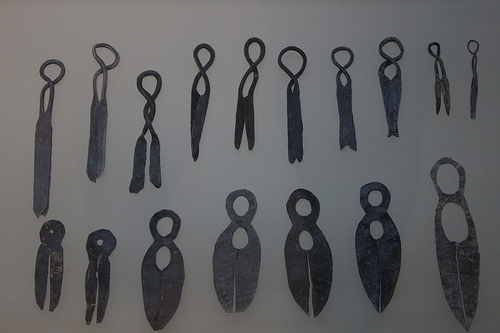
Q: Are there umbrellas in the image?
A: No, there are no umbrellas.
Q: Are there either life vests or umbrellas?
A: No, there are no umbrellas or life vests.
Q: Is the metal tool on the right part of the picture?
A: Yes, the tool is on the right of the image.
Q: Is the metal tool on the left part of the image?
A: No, the tool is on the right of the image.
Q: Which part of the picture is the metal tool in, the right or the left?
A: The tool is on the right of the image.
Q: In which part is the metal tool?
A: The tool is on the right of the image.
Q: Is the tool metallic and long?
A: Yes, the tool is metallic and long.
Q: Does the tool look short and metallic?
A: No, the tool is metallic but long.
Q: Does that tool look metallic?
A: Yes, the tool is metallic.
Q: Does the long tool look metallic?
A: Yes, the tool is metallic.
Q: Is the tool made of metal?
A: Yes, the tool is made of metal.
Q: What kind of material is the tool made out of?
A: The tool is made of metal.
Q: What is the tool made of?
A: The tool is made of metal.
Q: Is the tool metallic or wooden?
A: The tool is metallic.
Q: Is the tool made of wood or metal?
A: The tool is made of metal.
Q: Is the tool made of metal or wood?
A: The tool is made of metal.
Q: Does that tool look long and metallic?
A: Yes, the tool is long and metallic.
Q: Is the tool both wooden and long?
A: No, the tool is long but metallic.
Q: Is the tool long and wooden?
A: No, the tool is long but metallic.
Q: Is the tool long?
A: Yes, the tool is long.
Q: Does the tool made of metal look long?
A: Yes, the tool is long.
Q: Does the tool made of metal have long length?
A: Yes, the tool is long.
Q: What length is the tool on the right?
A: The tool is long.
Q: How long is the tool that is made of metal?
A: The tool is long.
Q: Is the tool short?
A: No, the tool is long.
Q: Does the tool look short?
A: No, the tool is long.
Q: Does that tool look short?
A: No, the tool is long.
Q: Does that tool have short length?
A: No, the tool is long.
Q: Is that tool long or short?
A: The tool is long.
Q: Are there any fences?
A: No, there are no fences.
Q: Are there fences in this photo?
A: No, there are no fences.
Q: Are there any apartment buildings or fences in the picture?
A: No, there are no fences or apartment buildings.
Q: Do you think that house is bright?
A: Yes, the house is bright.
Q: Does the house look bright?
A: Yes, the house is bright.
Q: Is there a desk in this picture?
A: No, there are no desks.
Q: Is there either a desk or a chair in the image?
A: No, there are no desks or chairs.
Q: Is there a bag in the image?
A: No, there are no bags.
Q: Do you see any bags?
A: No, there are no bags.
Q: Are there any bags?
A: No, there are no bags.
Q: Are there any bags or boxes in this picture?
A: No, there are no bags or boxes.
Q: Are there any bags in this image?
A: No, there are no bags.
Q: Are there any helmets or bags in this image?
A: No, there are no bags or helmets.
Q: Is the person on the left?
A: Yes, the person is on the left of the image.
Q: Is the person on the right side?
A: No, the person is on the left of the image.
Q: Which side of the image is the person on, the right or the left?
A: The person is on the left of the image.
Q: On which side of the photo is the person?
A: The person is on the left of the image.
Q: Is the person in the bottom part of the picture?
A: Yes, the person is in the bottom of the image.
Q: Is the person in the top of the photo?
A: No, the person is in the bottom of the image.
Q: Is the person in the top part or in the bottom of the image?
A: The person is in the bottom of the image.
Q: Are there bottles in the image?
A: No, there are no bottles.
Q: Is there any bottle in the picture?
A: No, there are no bottles.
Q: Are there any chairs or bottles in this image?
A: No, there are no bottles or chairs.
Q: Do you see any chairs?
A: No, there are no chairs.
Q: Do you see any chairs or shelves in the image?
A: No, there are no chairs or shelves.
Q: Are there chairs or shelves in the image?
A: No, there are no chairs or shelves.